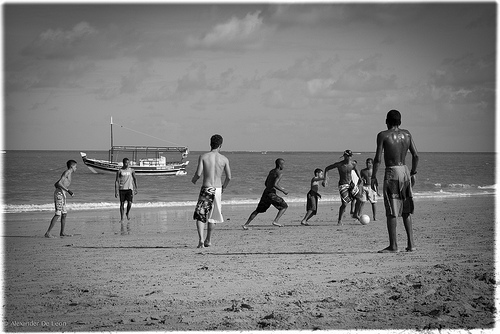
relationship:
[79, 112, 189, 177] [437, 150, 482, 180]
boat in water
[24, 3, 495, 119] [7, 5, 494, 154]
clouds in sky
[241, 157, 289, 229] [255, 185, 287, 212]
male wearing shorts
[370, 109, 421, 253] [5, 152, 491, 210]
black male facing water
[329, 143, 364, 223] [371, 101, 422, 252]
male facing male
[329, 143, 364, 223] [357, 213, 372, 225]
male kicking ball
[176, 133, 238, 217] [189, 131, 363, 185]
male with back to water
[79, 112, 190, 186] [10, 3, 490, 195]
boat in background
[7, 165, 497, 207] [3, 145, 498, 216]
wave on ocean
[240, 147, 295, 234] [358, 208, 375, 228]
male running after ball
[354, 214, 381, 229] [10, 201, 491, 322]
ball on beach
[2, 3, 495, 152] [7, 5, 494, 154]
clouds in sky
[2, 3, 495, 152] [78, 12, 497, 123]
clouds in sky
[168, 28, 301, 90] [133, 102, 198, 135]
white clouds in blue sky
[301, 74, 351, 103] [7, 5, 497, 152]
white clouds in blue sky